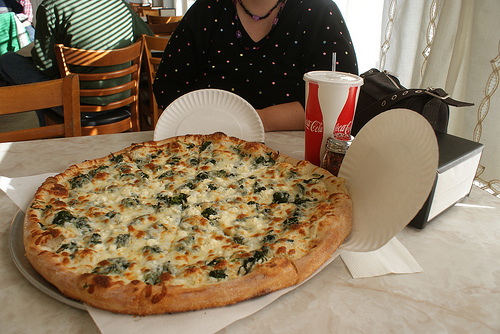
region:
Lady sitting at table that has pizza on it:
[155, 0, 360, 131]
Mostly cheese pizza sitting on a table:
[20, 130, 355, 315]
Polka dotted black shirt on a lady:
[151, 0, 357, 105]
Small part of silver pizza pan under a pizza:
[5, 205, 90, 311]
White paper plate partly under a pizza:
[341, 107, 442, 252]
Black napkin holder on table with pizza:
[416, 132, 481, 225]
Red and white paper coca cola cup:
[300, 67, 360, 163]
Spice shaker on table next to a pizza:
[317, 130, 352, 170]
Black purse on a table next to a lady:
[351, 65, 474, 136]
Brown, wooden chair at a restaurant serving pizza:
[54, 41, 146, 135]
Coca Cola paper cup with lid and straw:
[300, 49, 360, 169]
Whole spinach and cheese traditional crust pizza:
[20, 127, 357, 317]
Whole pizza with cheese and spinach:
[25, 127, 361, 317]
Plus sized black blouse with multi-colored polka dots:
[150, 3, 356, 125]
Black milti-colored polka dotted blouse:
[158, 5, 362, 111]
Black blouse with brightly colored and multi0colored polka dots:
[153, 3, 371, 119]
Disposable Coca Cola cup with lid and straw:
[299, 49, 359, 166]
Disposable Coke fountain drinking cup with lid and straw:
[301, 45, 362, 171]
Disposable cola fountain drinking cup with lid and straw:
[301, 46, 363, 172]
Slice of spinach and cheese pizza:
[153, 199, 295, 311]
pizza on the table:
[39, 118, 354, 314]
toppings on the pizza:
[115, 148, 258, 258]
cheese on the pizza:
[113, 200, 195, 265]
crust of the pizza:
[152, 266, 250, 313]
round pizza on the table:
[8, 119, 339, 326]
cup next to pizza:
[293, 58, 367, 150]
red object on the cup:
[290, 85, 338, 142]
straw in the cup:
[326, 45, 346, 78]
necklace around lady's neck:
[238, 3, 270, 35]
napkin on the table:
[368, 241, 433, 303]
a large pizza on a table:
[24, 125, 352, 315]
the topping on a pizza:
[145, 177, 193, 219]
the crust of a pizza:
[108, 272, 260, 319]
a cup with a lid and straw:
[299, 46, 367, 161]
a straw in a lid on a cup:
[303, 47, 361, 84]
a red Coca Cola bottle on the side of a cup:
[299, 79, 327, 164]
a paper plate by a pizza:
[153, 85, 263, 155]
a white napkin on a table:
[345, 243, 425, 284]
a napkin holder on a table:
[417, 136, 490, 226]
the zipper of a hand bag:
[363, 65, 475, 101]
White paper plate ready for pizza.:
[148, 83, 270, 148]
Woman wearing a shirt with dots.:
[147, 5, 342, 106]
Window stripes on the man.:
[55, 4, 137, 66]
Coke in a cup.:
[285, 46, 362, 166]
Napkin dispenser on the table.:
[424, 138, 484, 229]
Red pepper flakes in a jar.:
[316, 128, 356, 183]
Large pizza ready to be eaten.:
[20, 101, 350, 321]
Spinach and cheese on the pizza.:
[100, 135, 255, 256]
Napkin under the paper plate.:
[332, 238, 475, 285]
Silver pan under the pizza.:
[4, 190, 46, 318]